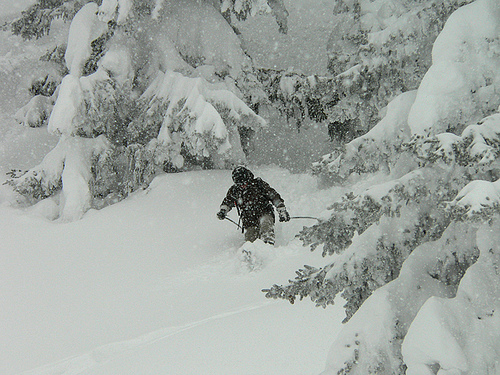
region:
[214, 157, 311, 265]
a man skiing in thick snow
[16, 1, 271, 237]
a tree completely covered in snow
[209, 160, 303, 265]
a black ski jacket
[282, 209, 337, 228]
a black ski pole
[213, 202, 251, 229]
a black ski pole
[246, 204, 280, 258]
grey ski pants on a man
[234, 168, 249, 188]
black googles on a man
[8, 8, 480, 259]
snow falling to the ground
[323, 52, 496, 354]
a tree covered with snow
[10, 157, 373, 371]
snow on the ground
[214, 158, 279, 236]
skier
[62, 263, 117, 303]
white snow on hill side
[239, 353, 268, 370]
white snow on hill side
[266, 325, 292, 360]
white snow on hill side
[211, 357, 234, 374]
white snow on hill side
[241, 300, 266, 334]
white snow on hill side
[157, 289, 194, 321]
white snow on hill side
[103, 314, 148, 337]
white snow on hill side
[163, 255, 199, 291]
white snow on hill side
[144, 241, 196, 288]
white snow on hill side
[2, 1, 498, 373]
Man is walking through very heavy snow.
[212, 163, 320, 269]
Man wearing heavy coat and gloves.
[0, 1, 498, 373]
Trees covered in snow.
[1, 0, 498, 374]
Man walking through blizzard in woods.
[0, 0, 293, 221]
Tree with snow on limbs.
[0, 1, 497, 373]
Man is walking through deep snow in woods.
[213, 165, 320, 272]
Person is wearing heavy coat and snow boots.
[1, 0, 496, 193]
It is snowing heavily in the woods.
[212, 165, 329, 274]
Man is holding sticks to help him walk through snow.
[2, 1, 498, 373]
Man with snow boots is walking through wooded area.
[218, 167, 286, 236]
a black jacket on a man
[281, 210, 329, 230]
a black ski pole in a man's hand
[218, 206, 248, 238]
a black ski pole in a man's hand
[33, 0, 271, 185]
a tree covered with snow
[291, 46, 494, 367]
a black ski pole in a man's hand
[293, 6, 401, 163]
a black ski pole in a man's hand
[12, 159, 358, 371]
the ground covered with snow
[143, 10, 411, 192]
snow falling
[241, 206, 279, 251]
grey pants on a person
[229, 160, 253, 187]
a black hood on a person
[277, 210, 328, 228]
black ski pole in a person's hand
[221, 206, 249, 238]
black ski pole in a person's hand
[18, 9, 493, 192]
snow falling down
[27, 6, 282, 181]
a snow covered tree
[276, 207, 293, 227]
black gloves on a person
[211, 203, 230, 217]
black gloves